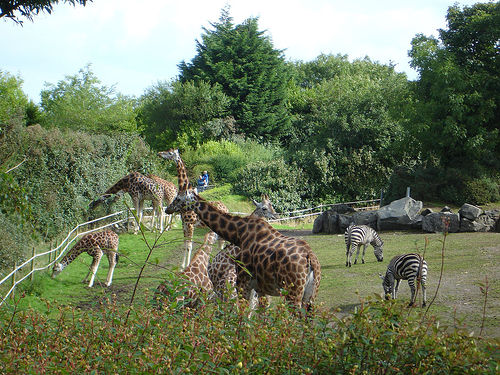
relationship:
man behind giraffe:
[195, 169, 208, 189] [156, 148, 225, 265]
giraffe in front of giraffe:
[164, 183, 323, 318] [156, 148, 225, 265]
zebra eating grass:
[382, 252, 430, 310] [290, 232, 499, 344]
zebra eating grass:
[345, 226, 384, 263] [290, 232, 499, 344]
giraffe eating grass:
[50, 230, 121, 288] [7, 223, 207, 318]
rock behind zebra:
[376, 196, 424, 228] [345, 226, 384, 263]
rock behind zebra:
[421, 211, 460, 234] [345, 226, 384, 263]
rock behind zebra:
[457, 202, 483, 219] [345, 226, 384, 263]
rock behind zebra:
[351, 208, 379, 231] [345, 226, 384, 263]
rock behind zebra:
[321, 208, 336, 234] [345, 226, 384, 263]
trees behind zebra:
[0, 3, 500, 212] [345, 226, 384, 263]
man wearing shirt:
[195, 169, 208, 189] [197, 175, 207, 185]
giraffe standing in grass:
[164, 183, 323, 318] [0, 268, 499, 374]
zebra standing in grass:
[382, 252, 430, 310] [290, 232, 499, 344]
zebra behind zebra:
[345, 226, 384, 263] [382, 252, 430, 310]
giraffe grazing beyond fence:
[102, 173, 180, 233] [3, 205, 183, 308]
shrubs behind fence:
[0, 126, 168, 276] [3, 205, 183, 308]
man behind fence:
[195, 169, 208, 189] [3, 205, 183, 308]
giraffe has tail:
[164, 183, 323, 318] [308, 256, 321, 310]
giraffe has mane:
[164, 183, 323, 318] [190, 189, 246, 221]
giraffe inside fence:
[50, 230, 121, 288] [3, 205, 183, 308]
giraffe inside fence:
[102, 173, 180, 233] [3, 205, 183, 308]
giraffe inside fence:
[152, 229, 215, 310] [3, 205, 183, 308]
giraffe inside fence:
[156, 148, 225, 265] [3, 205, 183, 308]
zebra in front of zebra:
[382, 252, 430, 310] [345, 226, 384, 263]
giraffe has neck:
[164, 183, 323, 318] [192, 195, 246, 248]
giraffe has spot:
[164, 183, 323, 318] [255, 230, 269, 241]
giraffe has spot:
[164, 183, 323, 318] [240, 235, 254, 250]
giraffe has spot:
[164, 183, 323, 318] [276, 250, 286, 261]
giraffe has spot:
[164, 183, 323, 318] [237, 225, 246, 236]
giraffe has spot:
[164, 183, 323, 318] [291, 253, 299, 262]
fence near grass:
[3, 205, 183, 308] [7, 223, 207, 318]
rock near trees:
[313, 208, 344, 233] [0, 3, 500, 212]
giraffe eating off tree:
[164, 183, 323, 318] [107, 200, 256, 325]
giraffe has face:
[164, 183, 323, 318] [163, 186, 196, 215]